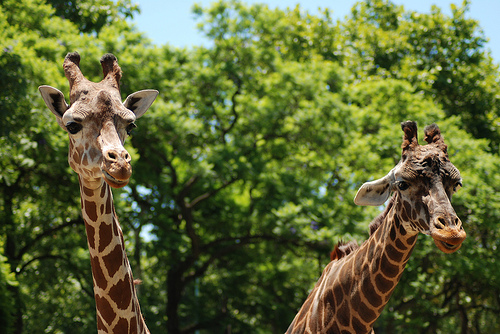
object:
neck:
[80, 187, 147, 333]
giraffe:
[37, 51, 159, 333]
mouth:
[101, 169, 130, 186]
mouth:
[441, 239, 462, 251]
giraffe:
[320, 120, 468, 334]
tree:
[153, 13, 324, 333]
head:
[354, 120, 466, 256]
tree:
[450, 281, 474, 330]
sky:
[111, 1, 216, 53]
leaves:
[342, 44, 370, 69]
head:
[37, 50, 160, 190]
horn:
[63, 49, 85, 87]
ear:
[40, 84, 68, 121]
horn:
[401, 120, 419, 150]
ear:
[354, 174, 396, 207]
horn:
[100, 50, 124, 87]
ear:
[122, 88, 159, 118]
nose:
[103, 149, 131, 163]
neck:
[329, 192, 419, 332]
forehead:
[402, 146, 449, 175]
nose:
[435, 214, 462, 229]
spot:
[99, 221, 113, 256]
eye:
[66, 122, 84, 134]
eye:
[396, 179, 411, 192]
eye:
[126, 123, 135, 137]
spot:
[90, 256, 107, 290]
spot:
[361, 265, 382, 311]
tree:
[3, 174, 27, 334]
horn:
[424, 119, 446, 150]